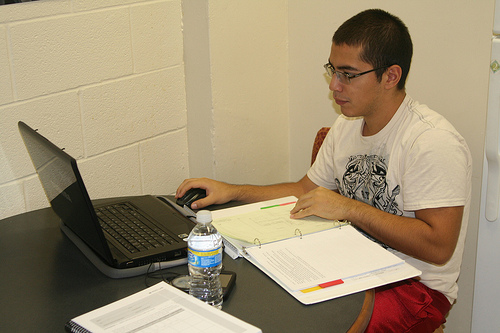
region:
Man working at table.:
[174, 8, 470, 331]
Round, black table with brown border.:
[0, 195, 375, 332]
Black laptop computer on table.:
[18, 120, 198, 280]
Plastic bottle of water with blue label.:
[186, 209, 223, 310]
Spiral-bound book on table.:
[64, 280, 264, 331]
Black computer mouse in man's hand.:
[175, 187, 205, 207]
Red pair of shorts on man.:
[364, 276, 451, 331]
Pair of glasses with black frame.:
[323, 61, 392, 85]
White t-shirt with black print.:
[306, 94, 473, 305]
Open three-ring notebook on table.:
[210, 194, 422, 305]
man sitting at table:
[178, 6, 495, 331]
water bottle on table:
[158, 182, 245, 332]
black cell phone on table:
[173, 257, 259, 317]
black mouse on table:
[155, 162, 228, 206]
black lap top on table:
[8, 107, 238, 288]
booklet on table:
[181, 175, 426, 331]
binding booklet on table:
[53, 271, 260, 331]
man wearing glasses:
[320, 37, 462, 96]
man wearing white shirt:
[302, 106, 499, 313]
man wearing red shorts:
[362, 240, 474, 331]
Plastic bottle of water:
[186, 209, 225, 305]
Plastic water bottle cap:
[192, 208, 216, 226]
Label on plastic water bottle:
[179, 242, 228, 265]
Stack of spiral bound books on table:
[57, 279, 264, 329]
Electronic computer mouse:
[174, 184, 219, 206]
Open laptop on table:
[14, 118, 232, 277]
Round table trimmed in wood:
[4, 192, 387, 330]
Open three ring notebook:
[194, 192, 424, 305]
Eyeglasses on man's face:
[309, 59, 407, 85]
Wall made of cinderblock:
[2, 2, 196, 222]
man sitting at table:
[128, 5, 487, 326]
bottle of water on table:
[161, 192, 251, 318]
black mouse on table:
[174, 154, 216, 229]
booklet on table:
[205, 191, 432, 328]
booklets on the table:
[45, 270, 272, 332]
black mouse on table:
[164, 142, 234, 239]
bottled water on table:
[181, 205, 242, 330]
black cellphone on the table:
[168, 245, 274, 308]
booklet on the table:
[57, 259, 283, 331]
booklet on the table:
[194, 176, 426, 328]